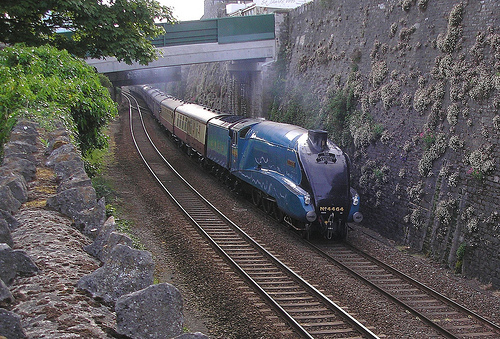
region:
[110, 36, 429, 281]
this is a train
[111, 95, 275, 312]
a set of train tracks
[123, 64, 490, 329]
train is on the tracks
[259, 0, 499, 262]
wall next to train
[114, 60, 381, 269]
Long train going down the tracks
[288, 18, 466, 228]
Wall has moss growing on it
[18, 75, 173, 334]
Rocks on the side of the tracks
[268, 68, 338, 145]
steam rising above the train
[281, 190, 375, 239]
Lights on the front of the train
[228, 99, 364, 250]
The train engine on the front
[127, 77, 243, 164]
the train cars behind the engine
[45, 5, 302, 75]
the shaft crossing the tracks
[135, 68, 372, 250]
a long train with cars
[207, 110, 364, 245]
a blue train engine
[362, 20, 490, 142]
plants growing on a cliff side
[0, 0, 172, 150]
large bushes on a ledge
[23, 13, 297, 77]
a tunnel between two cliffs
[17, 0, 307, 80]
a bridge with a roof and windows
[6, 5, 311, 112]
a tunnel that goes over a canyon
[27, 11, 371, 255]
a bridge with a train under it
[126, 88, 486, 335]
a train track with one train on it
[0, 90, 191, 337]
a stone wall on a ledge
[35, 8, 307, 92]
a brick tunnel over a trench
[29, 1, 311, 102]
a tunnel between two cliffs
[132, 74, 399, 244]
a long passenger train on the rails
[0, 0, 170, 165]
trees grow off the top of a ledge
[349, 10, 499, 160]
plants growing off the side of a cliff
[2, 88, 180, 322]
a brick path on a ledge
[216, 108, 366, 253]
a blue train engine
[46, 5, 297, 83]
a covered tunneled path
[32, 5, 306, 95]
a bridge with windows and a roof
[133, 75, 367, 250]
a long passenger train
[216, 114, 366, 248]
a blue train engine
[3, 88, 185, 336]
a tall stone wall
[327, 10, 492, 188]
plants growing on the side fo a cliff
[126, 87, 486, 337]
a pair of train tracks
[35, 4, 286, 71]
a modern looking tunnel bridge with windows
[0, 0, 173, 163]
trees growing by the side of a cliff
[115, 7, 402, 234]
a train travels under a tunnel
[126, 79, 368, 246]
train moving down the track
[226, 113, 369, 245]
blue engine on the train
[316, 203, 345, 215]
number on the front of the train